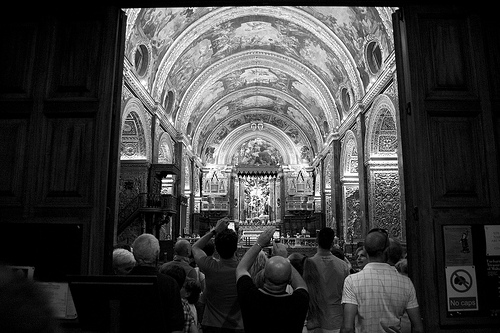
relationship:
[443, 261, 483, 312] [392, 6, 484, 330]
sign on wall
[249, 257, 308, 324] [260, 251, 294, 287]
back of a head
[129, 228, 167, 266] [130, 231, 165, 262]
head of hair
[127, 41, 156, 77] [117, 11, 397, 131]
hole on ceiling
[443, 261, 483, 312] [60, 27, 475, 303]
sign on a doorway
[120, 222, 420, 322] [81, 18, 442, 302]
crowd taking pictures in a church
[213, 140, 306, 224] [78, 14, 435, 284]
back of a church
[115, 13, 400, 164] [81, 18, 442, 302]
ceiling of a church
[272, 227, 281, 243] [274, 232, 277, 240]
camera phone taking a picture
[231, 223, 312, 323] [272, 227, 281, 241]
man with camera phone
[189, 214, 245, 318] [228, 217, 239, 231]
man with camera phone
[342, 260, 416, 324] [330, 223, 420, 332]
shirt on a man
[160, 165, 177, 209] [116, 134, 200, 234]
light on a wall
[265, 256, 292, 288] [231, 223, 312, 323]
bald head of man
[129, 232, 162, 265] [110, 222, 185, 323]
head of man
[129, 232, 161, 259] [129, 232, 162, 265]
hair on head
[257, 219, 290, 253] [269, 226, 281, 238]
hands holding phone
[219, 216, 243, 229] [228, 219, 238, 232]
hands holding camera phone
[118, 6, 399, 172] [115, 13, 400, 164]
artwork on ceiling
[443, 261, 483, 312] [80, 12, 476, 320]
sign on wall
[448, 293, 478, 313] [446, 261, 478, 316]
writing on sign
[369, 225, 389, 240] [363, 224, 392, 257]
glasses on person's head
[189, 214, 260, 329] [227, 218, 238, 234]
man holding phone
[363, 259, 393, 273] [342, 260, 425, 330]
collar on shirt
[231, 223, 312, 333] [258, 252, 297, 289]
man has bald head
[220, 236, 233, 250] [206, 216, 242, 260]
back of person's head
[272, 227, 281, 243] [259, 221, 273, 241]
camera phone on hands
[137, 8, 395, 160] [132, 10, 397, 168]
artwork on ceiling